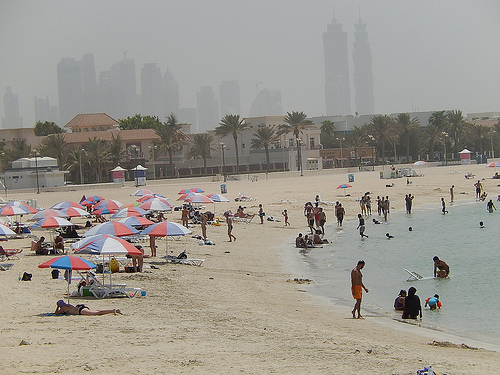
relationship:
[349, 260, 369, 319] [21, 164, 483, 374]
man on beach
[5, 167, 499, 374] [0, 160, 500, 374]
dirt on beach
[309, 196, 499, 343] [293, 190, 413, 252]
water next to people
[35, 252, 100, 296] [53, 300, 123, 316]
umbrella above woman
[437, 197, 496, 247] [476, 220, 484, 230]
person has head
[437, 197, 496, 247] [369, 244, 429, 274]
person in water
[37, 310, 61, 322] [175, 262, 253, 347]
shadow on sand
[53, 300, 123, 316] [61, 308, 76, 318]
woman on stomach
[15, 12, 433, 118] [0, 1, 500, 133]
buildings behind fog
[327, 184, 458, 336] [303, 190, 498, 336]
people in water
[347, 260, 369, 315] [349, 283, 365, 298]
man in trunks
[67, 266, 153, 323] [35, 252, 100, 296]
chairs under umbrella